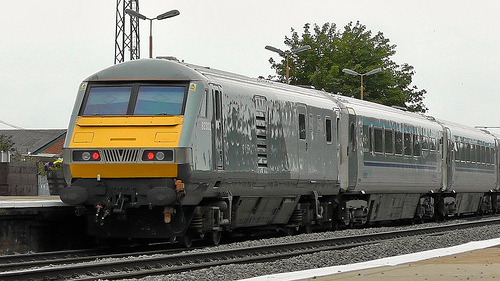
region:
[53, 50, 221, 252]
Section of a train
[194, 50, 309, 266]
Section of a train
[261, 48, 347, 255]
Section of a train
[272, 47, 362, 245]
Section of a train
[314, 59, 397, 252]
Section of a train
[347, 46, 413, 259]
Section of a train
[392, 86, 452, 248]
Section of a train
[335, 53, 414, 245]
Section of a train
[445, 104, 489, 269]
Section of a train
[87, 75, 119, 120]
Small window on a train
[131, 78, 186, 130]
Small window on a train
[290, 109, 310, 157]
Small window on a train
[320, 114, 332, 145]
Small window on a train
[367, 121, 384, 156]
Small window on a train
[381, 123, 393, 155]
Small window on a train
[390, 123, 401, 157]
Small window on a train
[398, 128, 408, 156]
Small window on a train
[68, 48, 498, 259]
Large grey train on the tracks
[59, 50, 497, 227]
A passenger train barrels by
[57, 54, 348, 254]
Engine car of an electric train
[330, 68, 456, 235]
passenger car of a train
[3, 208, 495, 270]
Two sets of train tracts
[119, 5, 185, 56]
a light pole above the train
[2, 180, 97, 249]
A train station loading dock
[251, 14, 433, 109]
AS tree behind the train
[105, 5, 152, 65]
A metal tower rises above the train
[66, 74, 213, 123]
front windows of the train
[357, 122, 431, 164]
a line of windows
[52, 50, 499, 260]
a train on tracks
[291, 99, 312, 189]
a door of the train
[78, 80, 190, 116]
windshield of the train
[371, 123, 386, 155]
a window on the train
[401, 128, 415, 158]
a window of the train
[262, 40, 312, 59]
lights on the post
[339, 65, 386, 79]
lights on the post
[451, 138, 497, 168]
windows of the train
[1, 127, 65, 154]
a roof of the building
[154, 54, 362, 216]
the train is gray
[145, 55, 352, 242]
the train is gray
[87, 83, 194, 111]
windshield of the train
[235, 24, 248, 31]
the sky is foggy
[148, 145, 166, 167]
light on the train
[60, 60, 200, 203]
front of the train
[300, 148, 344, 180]
the train is silver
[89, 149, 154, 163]
red signals on front of train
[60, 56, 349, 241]
engine car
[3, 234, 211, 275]
tracks in front of train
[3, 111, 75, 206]
build to left of train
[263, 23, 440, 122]
tops of trees behind train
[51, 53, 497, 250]
yellow and gray train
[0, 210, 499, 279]
Train trucks on the ground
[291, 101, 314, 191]
Door is closed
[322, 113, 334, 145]
Window on the train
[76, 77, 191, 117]
Windshield on the train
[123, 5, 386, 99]
Line of lights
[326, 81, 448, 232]
Train car of the train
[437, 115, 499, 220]
Train car of the train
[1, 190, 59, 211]
Platform of the train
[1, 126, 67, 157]
Gray roof top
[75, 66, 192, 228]
yellow front of train